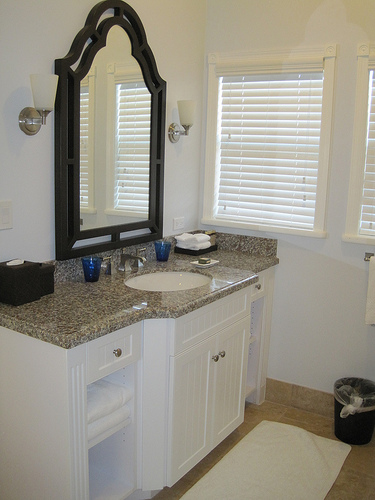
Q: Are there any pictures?
A: No, there are no pictures.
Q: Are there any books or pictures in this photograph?
A: No, there are no pictures or books.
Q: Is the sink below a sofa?
A: No, the sink is below the mirror.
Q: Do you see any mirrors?
A: Yes, there is a mirror.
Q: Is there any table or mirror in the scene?
A: Yes, there is a mirror.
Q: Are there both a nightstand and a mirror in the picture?
A: No, there is a mirror but no nightstands.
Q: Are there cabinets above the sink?
A: No, there is a mirror above the sink.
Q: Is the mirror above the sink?
A: Yes, the mirror is above the sink.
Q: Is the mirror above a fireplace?
A: No, the mirror is above the sink.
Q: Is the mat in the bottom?
A: Yes, the mat is in the bottom of the image.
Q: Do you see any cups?
A: Yes, there is a cup.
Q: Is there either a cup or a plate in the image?
A: Yes, there is a cup.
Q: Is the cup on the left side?
A: Yes, the cup is on the left of the image.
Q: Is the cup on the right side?
A: No, the cup is on the left of the image.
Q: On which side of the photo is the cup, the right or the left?
A: The cup is on the left of the image.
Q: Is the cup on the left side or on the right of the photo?
A: The cup is on the left of the image.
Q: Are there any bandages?
A: No, there are no bandages.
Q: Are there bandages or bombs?
A: No, there are no bandages or bombs.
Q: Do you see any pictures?
A: No, there are no pictures.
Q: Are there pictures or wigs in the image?
A: No, there are no pictures or wigs.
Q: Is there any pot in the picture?
A: No, there are no pots.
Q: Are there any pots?
A: No, there are no pots.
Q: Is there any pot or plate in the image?
A: No, there are no pots or plates.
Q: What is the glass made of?
A: The glass is made of glass.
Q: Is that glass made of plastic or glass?
A: The glass is made of glass.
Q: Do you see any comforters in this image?
A: No, there are no comforters.